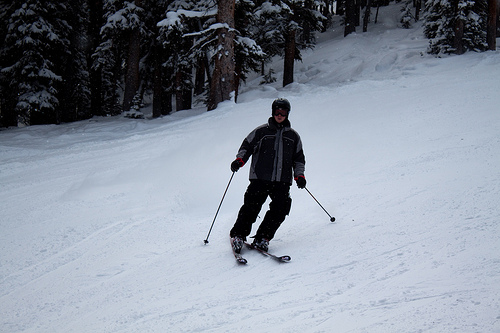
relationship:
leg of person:
[222, 185, 267, 240] [204, 97, 305, 267]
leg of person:
[255, 195, 296, 247] [204, 97, 305, 267]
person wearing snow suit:
[204, 97, 305, 267] [230, 118, 307, 242]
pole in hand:
[197, 169, 236, 242] [229, 160, 243, 173]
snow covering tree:
[158, 9, 219, 26] [170, 0, 198, 113]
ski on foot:
[228, 226, 250, 265] [231, 232, 247, 250]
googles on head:
[272, 107, 289, 117] [271, 99, 291, 124]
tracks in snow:
[127, 243, 499, 332] [4, 35, 499, 332]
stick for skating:
[197, 169, 236, 242] [192, 100, 345, 270]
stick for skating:
[302, 185, 340, 224] [192, 100, 345, 270]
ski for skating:
[228, 226, 250, 265] [192, 100, 345, 270]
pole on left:
[197, 169, 236, 242] [1, 1, 267, 332]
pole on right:
[302, 185, 340, 224] [268, 1, 498, 332]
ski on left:
[228, 226, 250, 265] [1, 1, 267, 332]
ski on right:
[249, 242, 293, 264] [268, 1, 498, 332]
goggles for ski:
[272, 107, 289, 117] [199, 84, 345, 270]